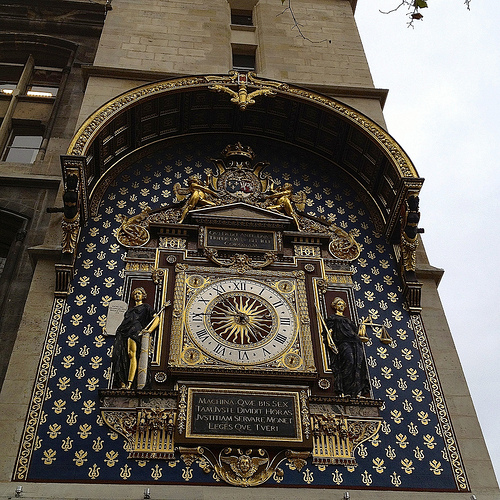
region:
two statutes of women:
[105, 280, 370, 396]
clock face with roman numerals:
[186, 270, 293, 366]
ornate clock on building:
[90, 148, 385, 498]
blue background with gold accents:
[45, 134, 435, 493]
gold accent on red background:
[212, 297, 269, 344]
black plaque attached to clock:
[187, 390, 296, 442]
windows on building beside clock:
[0, 26, 67, 196]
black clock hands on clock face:
[182, 281, 247, 328]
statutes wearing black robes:
[105, 275, 365, 392]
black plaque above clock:
[194, 220, 290, 260]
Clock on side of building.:
[172, 262, 318, 386]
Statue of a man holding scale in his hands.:
[326, 292, 393, 394]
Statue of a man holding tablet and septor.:
[104, 277, 172, 393]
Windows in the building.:
[217, 5, 267, 78]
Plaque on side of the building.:
[181, 384, 309, 447]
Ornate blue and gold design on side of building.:
[42, 139, 460, 496]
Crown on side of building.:
[217, 138, 265, 167]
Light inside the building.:
[0, 69, 58, 101]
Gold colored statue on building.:
[174, 169, 211, 221]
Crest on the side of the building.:
[216, 160, 266, 206]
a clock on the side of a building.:
[170, 262, 319, 377]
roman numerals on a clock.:
[233, 276, 251, 296]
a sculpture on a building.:
[168, 185, 331, 255]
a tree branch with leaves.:
[373, 0, 477, 30]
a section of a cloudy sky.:
[355, 3, 497, 498]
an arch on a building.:
[50, 64, 434, 316]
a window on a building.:
[19, 62, 70, 112]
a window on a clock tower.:
[0, 60, 73, 147]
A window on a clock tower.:
[228, 2, 268, 78]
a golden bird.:
[202, 67, 284, 115]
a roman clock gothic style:
[187, 274, 300, 367]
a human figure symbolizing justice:
[318, 290, 390, 398]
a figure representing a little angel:
[221, 446, 269, 483]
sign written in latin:
[194, 394, 298, 436]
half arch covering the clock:
[61, 75, 435, 224]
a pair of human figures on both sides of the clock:
[118, 285, 375, 392]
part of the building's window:
[0, 32, 72, 162]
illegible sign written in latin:
[201, 224, 276, 251]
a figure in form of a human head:
[232, 252, 248, 268]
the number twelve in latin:
[232, 279, 249, 293]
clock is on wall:
[169, 257, 303, 368]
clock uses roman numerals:
[195, 302, 275, 347]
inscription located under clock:
[188, 386, 299, 445]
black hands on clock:
[220, 294, 263, 337]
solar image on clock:
[200, 273, 295, 360]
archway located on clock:
[89, 60, 408, 241]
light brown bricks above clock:
[117, 4, 294, 79]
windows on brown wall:
[0, 67, 77, 163]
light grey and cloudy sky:
[385, 52, 499, 225]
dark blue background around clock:
[93, 181, 409, 459]